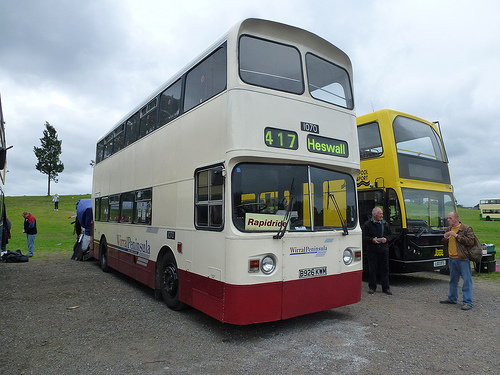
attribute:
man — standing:
[364, 203, 396, 299]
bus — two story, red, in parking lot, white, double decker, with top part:
[91, 16, 366, 326]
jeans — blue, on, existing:
[445, 257, 473, 304]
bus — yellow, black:
[356, 108, 464, 275]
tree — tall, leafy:
[31, 121, 66, 197]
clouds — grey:
[1, 2, 500, 210]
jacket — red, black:
[23, 212, 38, 237]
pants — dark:
[367, 241, 391, 289]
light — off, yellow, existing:
[260, 253, 277, 274]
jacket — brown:
[439, 223, 476, 259]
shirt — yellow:
[447, 223, 464, 260]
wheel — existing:
[157, 249, 187, 313]